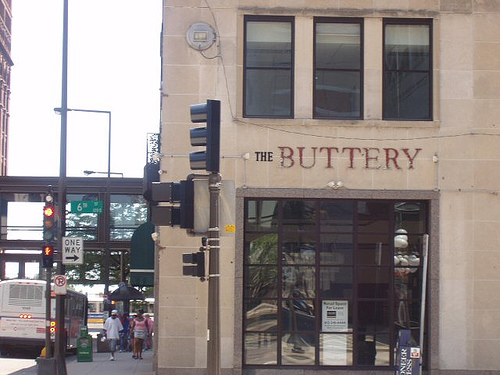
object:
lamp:
[189, 100, 220, 171]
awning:
[130, 221, 154, 285]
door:
[243, 198, 429, 375]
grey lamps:
[54, 107, 61, 112]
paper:
[321, 300, 348, 331]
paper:
[321, 333, 346, 366]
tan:
[441, 203, 473, 223]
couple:
[105, 309, 147, 359]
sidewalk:
[10, 351, 156, 375]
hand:
[43, 246, 49, 257]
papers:
[322, 300, 347, 365]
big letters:
[278, 146, 423, 170]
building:
[156, 0, 500, 375]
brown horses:
[240, 16, 433, 121]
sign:
[62, 237, 83, 263]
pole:
[205, 168, 223, 375]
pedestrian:
[104, 310, 124, 360]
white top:
[102, 317, 123, 340]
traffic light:
[43, 195, 54, 241]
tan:
[441, 70, 474, 100]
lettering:
[255, 152, 273, 162]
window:
[382, 18, 433, 122]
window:
[312, 16, 362, 120]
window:
[243, 15, 292, 120]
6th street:
[71, 200, 104, 213]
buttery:
[255, 146, 422, 169]